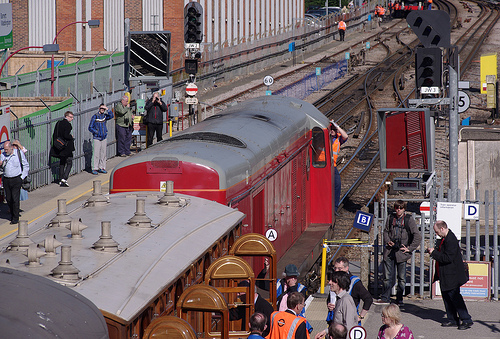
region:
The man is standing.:
[421, 215, 482, 336]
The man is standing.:
[371, 189, 422, 314]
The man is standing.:
[110, 92, 139, 159]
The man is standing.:
[140, 88, 170, 154]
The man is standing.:
[82, 93, 117, 187]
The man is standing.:
[43, 106, 80, 189]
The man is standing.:
[0, 135, 37, 227]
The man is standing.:
[332, 10, 352, 45]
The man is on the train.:
[111, 84, 354, 279]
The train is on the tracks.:
[0, 16, 430, 337]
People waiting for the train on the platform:
[0, 32, 232, 218]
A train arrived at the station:
[0, 77, 373, 322]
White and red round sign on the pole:
[182, 76, 204, 126]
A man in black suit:
[418, 206, 480, 337]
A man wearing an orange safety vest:
[255, 275, 314, 337]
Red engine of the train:
[105, 67, 378, 244]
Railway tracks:
[337, 3, 489, 135]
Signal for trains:
[180, 0, 212, 99]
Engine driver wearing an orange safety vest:
[296, 96, 358, 236]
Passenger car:
[0, 172, 266, 323]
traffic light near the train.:
[189, 7, 201, 40]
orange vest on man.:
[274, 319, 289, 334]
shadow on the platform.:
[417, 305, 432, 317]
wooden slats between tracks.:
[362, 176, 374, 191]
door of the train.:
[315, 176, 326, 214]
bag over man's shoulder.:
[47, 133, 65, 161]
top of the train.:
[208, 119, 264, 125]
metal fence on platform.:
[484, 203, 495, 240]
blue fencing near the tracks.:
[297, 78, 313, 91]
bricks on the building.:
[169, 15, 179, 30]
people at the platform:
[31, 94, 201, 163]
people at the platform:
[271, 235, 412, 333]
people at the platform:
[3, 93, 131, 226]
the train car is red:
[174, 141, 355, 307]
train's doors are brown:
[126, 228, 333, 337]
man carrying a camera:
[378, 200, 425, 290]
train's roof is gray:
[131, 78, 362, 188]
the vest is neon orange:
[258, 300, 311, 335]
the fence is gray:
[20, 107, 57, 191]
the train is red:
[207, 144, 337, 257]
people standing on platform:
[3, 86, 163, 213]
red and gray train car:
[109, 99, 336, 295]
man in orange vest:
[263, 294, 311, 337]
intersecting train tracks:
[326, 62, 408, 173]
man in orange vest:
[314, 124, 346, 174]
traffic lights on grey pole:
[414, 49, 459, 199]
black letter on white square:
[463, 201, 480, 221]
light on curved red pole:
[50, 17, 101, 44]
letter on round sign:
[264, 226, 280, 241]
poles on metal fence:
[18, 78, 172, 183]